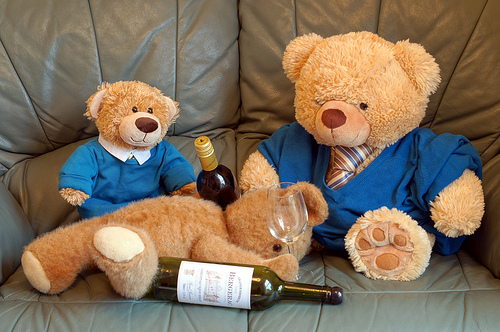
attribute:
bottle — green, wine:
[151, 251, 346, 315]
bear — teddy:
[232, 21, 495, 298]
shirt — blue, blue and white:
[260, 116, 484, 253]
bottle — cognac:
[192, 134, 234, 205]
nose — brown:
[316, 106, 348, 129]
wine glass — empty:
[263, 185, 335, 257]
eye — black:
[358, 101, 367, 111]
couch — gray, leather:
[6, 1, 498, 330]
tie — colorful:
[326, 145, 378, 190]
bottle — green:
[189, 134, 242, 198]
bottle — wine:
[140, 252, 349, 309]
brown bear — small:
[58, 79, 200, 218]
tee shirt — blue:
[79, 144, 188, 219]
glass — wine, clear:
[264, 179, 316, 286]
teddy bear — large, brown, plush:
[246, 27, 486, 279]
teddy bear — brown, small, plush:
[60, 78, 204, 215]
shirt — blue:
[258, 120, 480, 242]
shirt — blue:
[61, 137, 196, 215]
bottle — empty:
[174, 245, 334, 322]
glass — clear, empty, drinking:
[262, 182, 317, 277]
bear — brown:
[253, 33, 483, 275]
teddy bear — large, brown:
[286, 40, 483, 275]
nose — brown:
[321, 108, 346, 126]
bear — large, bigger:
[233, 30, 483, 288]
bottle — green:
[153, 254, 367, 321]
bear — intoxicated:
[38, 176, 302, 299]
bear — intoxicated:
[21, 163, 371, 313]